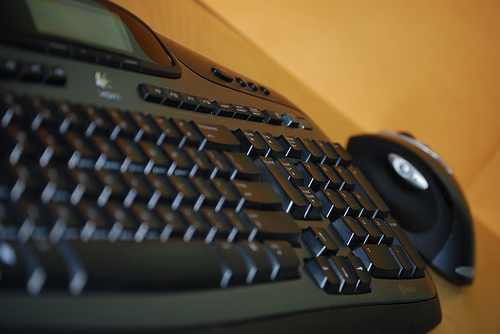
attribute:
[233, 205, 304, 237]
shift key — black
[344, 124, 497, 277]
mouse — black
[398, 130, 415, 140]
scroll wheel — blurry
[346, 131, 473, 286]
mouse — black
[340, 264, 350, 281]
arrow — pointing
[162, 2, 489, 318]
desk — tan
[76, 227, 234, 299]
space bar — black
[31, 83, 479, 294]
keyboard — black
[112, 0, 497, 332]
desk — wood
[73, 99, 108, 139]
keys — black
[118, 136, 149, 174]
keys — black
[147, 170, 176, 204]
keys — black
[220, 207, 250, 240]
keys — black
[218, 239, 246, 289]
keys — black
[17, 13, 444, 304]
computer keyboard — black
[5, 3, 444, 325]
keyboard — black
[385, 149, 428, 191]
button — silver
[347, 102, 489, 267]
mouse — black